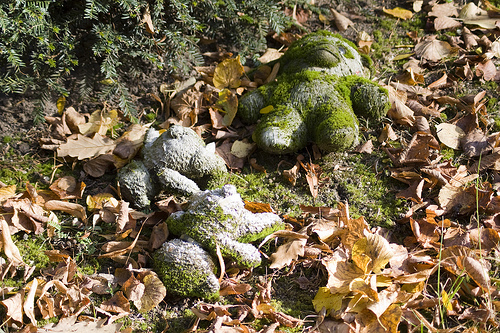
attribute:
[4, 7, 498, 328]
leaves — dried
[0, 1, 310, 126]
tree — evergreen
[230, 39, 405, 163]
animal — stuffed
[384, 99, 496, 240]
leaves — fallen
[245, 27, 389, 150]
animal — stuffed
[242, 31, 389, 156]
animals — forgotten, stuffed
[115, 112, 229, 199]
animal — stuffed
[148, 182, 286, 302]
animal — stuffed